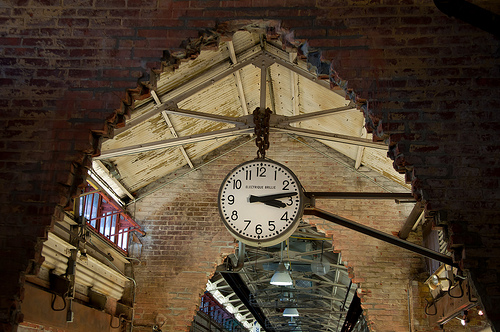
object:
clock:
[218, 157, 315, 249]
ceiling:
[84, 19, 416, 210]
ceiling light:
[270, 241, 293, 285]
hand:
[250, 192, 299, 204]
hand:
[250, 195, 286, 208]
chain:
[252, 106, 273, 159]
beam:
[92, 23, 411, 207]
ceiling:
[186, 218, 370, 332]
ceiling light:
[282, 308, 300, 316]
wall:
[0, 0, 499, 332]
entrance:
[6, 19, 500, 332]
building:
[0, 0, 499, 332]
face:
[220, 161, 301, 240]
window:
[116, 214, 130, 253]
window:
[98, 197, 118, 244]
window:
[78, 184, 140, 256]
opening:
[189, 219, 370, 331]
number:
[256, 167, 266, 178]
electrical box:
[66, 310, 74, 322]